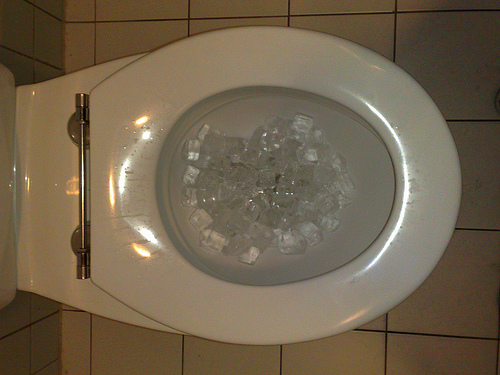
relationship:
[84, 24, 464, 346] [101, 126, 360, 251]
lid with water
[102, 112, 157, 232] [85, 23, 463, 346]
liquid on seat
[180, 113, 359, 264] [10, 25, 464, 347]
ice in toilet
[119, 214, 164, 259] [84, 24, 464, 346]
glare on lid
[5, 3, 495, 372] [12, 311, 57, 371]
bathroom tiled wall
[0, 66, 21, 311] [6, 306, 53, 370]
tank against wall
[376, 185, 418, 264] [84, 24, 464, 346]
reflection on lid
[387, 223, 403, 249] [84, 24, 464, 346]
light on lid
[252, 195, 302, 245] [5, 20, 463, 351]
ice in toilet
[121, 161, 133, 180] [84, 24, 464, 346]
water on lid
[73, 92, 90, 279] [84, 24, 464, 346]
hinge on lid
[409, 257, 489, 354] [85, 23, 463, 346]
floor beneath seat